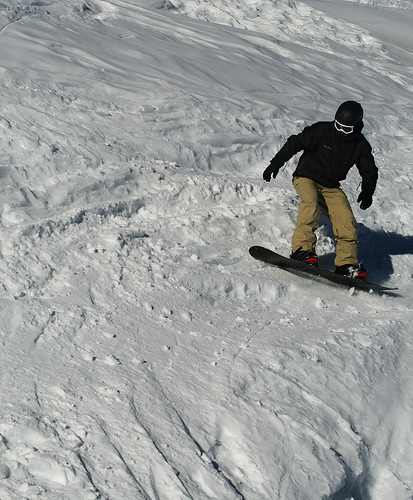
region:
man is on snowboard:
[243, 36, 399, 366]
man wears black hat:
[336, 97, 374, 137]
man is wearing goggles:
[313, 103, 372, 155]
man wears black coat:
[306, 95, 412, 187]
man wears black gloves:
[263, 157, 286, 184]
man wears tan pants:
[298, 166, 364, 285]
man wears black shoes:
[257, 231, 367, 283]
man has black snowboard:
[239, 231, 395, 302]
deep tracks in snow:
[56, 150, 336, 485]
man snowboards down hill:
[87, 65, 393, 492]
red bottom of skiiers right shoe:
[304, 254, 322, 268]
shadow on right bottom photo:
[310, 426, 412, 494]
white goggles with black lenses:
[324, 112, 358, 140]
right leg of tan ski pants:
[284, 173, 322, 240]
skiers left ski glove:
[359, 182, 375, 214]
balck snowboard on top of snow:
[257, 239, 399, 316]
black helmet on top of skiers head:
[316, 58, 375, 138]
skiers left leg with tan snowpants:
[323, 186, 367, 263]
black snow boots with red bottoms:
[336, 250, 379, 292]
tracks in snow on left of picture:
[29, 175, 206, 239]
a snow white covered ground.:
[23, 88, 244, 424]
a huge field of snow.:
[16, 59, 225, 338]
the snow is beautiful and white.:
[5, 69, 206, 295]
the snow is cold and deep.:
[36, 42, 170, 386]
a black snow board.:
[244, 241, 391, 282]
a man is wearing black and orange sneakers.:
[273, 242, 369, 273]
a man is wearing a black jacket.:
[309, 138, 343, 168]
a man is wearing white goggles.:
[329, 118, 354, 130]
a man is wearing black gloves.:
[256, 154, 282, 177]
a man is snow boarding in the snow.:
[109, 33, 410, 397]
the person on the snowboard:
[253, 76, 401, 329]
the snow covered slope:
[88, 16, 249, 159]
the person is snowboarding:
[220, 80, 402, 316]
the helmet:
[330, 97, 361, 122]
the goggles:
[331, 119, 366, 134]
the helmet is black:
[327, 100, 368, 117]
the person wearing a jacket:
[270, 106, 389, 181]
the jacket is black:
[280, 118, 384, 180]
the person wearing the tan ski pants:
[278, 173, 377, 263]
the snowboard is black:
[223, 240, 411, 306]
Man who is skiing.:
[216, 56, 411, 479]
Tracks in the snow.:
[47, 342, 288, 491]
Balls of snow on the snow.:
[69, 320, 155, 391]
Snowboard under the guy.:
[230, 182, 411, 328]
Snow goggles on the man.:
[306, 95, 363, 136]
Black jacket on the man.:
[245, 93, 391, 219]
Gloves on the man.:
[267, 151, 295, 201]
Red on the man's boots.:
[283, 236, 362, 279]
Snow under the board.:
[236, 231, 406, 327]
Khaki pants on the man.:
[274, 131, 412, 290]